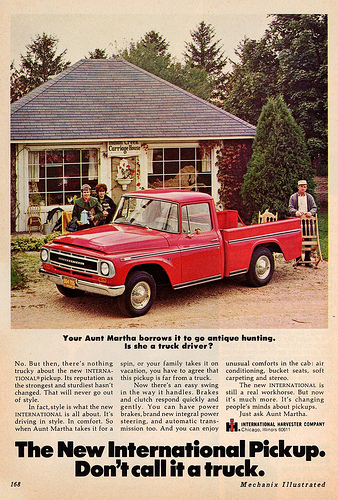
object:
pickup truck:
[39, 187, 305, 317]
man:
[288, 178, 318, 267]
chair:
[293, 212, 324, 270]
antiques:
[79, 208, 91, 226]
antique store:
[9, 58, 262, 232]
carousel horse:
[152, 164, 200, 191]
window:
[144, 144, 212, 198]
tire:
[119, 269, 157, 320]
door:
[110, 156, 137, 214]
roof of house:
[11, 58, 261, 142]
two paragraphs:
[12, 354, 219, 433]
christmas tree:
[239, 93, 320, 225]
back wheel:
[247, 246, 275, 288]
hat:
[296, 179, 308, 186]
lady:
[72, 183, 105, 233]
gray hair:
[79, 184, 92, 192]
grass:
[314, 206, 328, 261]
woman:
[93, 183, 118, 226]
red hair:
[95, 183, 108, 194]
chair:
[27, 203, 44, 235]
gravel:
[11, 251, 328, 329]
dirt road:
[10, 253, 328, 328]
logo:
[225, 418, 240, 433]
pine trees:
[264, 14, 328, 178]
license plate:
[63, 277, 77, 289]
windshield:
[113, 195, 179, 234]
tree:
[219, 72, 285, 130]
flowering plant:
[33, 151, 99, 169]